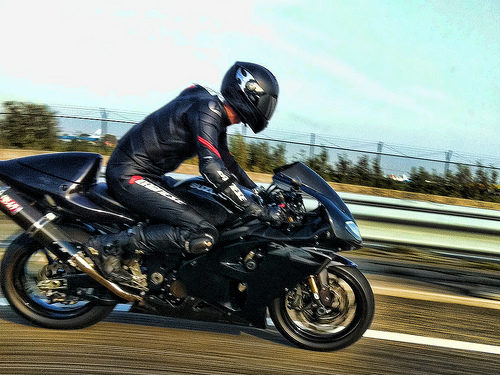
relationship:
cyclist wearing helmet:
[82, 61, 288, 283] [221, 62, 279, 134]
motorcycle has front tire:
[0, 151, 375, 351] [269, 254, 376, 350]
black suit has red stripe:
[106, 83, 263, 252] [197, 134, 222, 157]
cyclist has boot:
[82, 61, 288, 283] [86, 221, 145, 282]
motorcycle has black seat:
[0, 151, 375, 351] [90, 182, 133, 212]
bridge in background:
[1, 101, 500, 175] [0, 0, 499, 203]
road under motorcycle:
[0, 211, 499, 374] [0, 151, 375, 351]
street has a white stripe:
[0, 211, 499, 374] [0, 297, 499, 355]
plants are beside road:
[0, 102, 499, 202] [0, 211, 499, 374]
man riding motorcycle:
[82, 61, 288, 283] [0, 151, 375, 351]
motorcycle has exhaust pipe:
[0, 151, 375, 351] [0, 181, 143, 300]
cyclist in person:
[82, 61, 288, 283] [82, 61, 288, 284]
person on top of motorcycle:
[82, 61, 288, 283] [0, 151, 375, 351]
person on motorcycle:
[82, 61, 288, 283] [0, 151, 375, 351]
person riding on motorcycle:
[82, 61, 288, 283] [0, 151, 375, 351]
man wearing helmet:
[82, 61, 288, 283] [221, 62, 279, 134]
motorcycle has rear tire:
[0, 151, 375, 351] [0, 230, 117, 329]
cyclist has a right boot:
[82, 61, 288, 283] [86, 221, 145, 282]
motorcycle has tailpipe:
[0, 151, 375, 351] [0, 181, 143, 300]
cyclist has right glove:
[82, 61, 288, 283] [201, 156, 284, 225]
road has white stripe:
[0, 211, 499, 374] [0, 297, 499, 355]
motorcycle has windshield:
[0, 151, 375, 351] [273, 161, 354, 219]